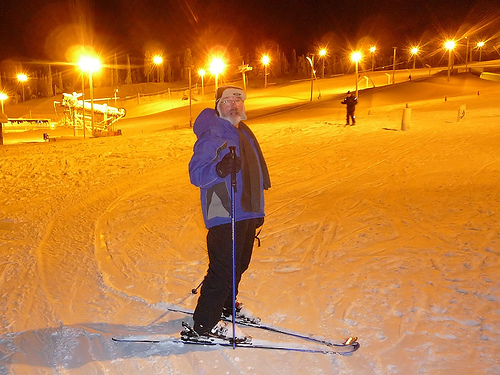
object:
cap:
[214, 83, 250, 123]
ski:
[110, 334, 362, 363]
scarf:
[234, 120, 272, 215]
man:
[338, 88, 360, 128]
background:
[0, 0, 499, 374]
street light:
[70, 48, 105, 135]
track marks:
[31, 189, 149, 336]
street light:
[348, 51, 362, 101]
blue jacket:
[186, 107, 271, 232]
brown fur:
[213, 84, 246, 101]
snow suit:
[340, 95, 358, 126]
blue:
[230, 272, 235, 314]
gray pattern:
[199, 177, 231, 218]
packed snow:
[29, 160, 191, 338]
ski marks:
[89, 189, 140, 285]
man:
[187, 84, 266, 344]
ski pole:
[228, 146, 243, 350]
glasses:
[213, 96, 247, 105]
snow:
[6, 84, 499, 315]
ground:
[0, 72, 499, 375]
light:
[9, 69, 32, 85]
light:
[150, 55, 166, 67]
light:
[207, 54, 230, 76]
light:
[258, 50, 275, 66]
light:
[313, 43, 331, 59]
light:
[405, 47, 419, 58]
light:
[438, 34, 460, 56]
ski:
[165, 303, 357, 347]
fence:
[82, 77, 250, 107]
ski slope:
[0, 92, 499, 375]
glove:
[214, 152, 242, 180]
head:
[214, 85, 246, 126]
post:
[88, 75, 94, 140]